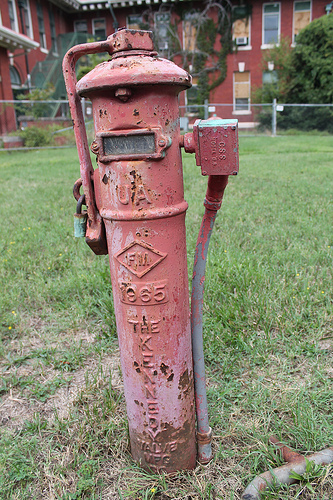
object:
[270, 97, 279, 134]
post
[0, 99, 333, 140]
fence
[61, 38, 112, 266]
handle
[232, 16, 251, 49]
window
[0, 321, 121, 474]
dirt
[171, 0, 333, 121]
wall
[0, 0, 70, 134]
wall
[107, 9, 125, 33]
wall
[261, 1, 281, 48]
trim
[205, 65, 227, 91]
vines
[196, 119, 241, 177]
box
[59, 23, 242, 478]
utility box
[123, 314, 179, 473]
manufacturer identification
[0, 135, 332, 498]
ground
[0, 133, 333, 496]
grass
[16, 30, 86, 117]
stairway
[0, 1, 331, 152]
building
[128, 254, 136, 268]
lettering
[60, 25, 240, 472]
fire hydrant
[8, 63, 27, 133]
arched entry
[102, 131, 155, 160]
information window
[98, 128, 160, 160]
box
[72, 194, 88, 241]
lock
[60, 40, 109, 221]
lever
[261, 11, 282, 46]
window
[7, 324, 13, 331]
flowers